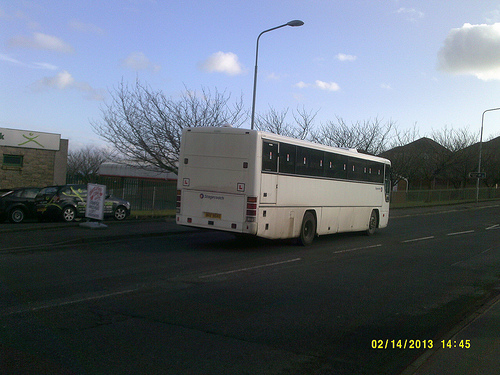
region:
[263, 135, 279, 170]
black window on bus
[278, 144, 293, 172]
black window on bus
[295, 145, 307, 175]
black window on bus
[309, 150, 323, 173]
black window on bus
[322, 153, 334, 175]
black window on bus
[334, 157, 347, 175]
black window on bus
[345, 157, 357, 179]
black window on bus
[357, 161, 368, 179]
black window on bus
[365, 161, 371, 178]
black window on bus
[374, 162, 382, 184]
black window on bus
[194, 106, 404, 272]
white bus on road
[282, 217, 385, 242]
black wheels on bus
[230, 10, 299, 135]
light pole behind bus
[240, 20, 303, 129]
light pole is grey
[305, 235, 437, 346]
road is dark grey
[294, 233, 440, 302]
white lines on road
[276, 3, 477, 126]
white and blue sky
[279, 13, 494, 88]
white clouds in sky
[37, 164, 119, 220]
green hybrid is parked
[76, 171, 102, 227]
white sign in front of hybrid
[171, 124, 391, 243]
white bus in street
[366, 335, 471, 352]
yellow time date stamp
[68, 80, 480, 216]
leafless brown trees in background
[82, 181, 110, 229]
large white sign on sidewalk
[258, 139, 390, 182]
bus has black tinted windows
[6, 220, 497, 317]
white lines painted in street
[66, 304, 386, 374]
large crack in street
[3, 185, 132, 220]
cars parked in parking lot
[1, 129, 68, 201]
brick building behind cars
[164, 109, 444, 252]
the bus is white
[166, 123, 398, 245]
the bus is white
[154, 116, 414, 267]
the bus is white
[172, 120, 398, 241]
the bus is white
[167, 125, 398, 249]
the bus is white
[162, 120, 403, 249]
the bus is white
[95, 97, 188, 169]
the tree is bare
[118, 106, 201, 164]
the tree is bare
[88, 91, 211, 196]
the tree is bare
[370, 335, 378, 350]
yellow print style number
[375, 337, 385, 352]
yellow print style number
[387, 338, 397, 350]
yellow print style number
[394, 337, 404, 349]
yellow print style number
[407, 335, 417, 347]
yellow print style number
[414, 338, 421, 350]
yellow print style number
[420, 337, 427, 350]
yellow print style number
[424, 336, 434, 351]
yellow print style number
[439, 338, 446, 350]
yellow print style number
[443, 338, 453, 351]
yellow print style number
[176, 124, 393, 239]
the bus is white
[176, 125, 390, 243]
the bus is dirty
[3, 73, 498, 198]
the trees are bare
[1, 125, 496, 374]
the bus on the road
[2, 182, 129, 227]
the cars are parked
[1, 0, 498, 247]
the blue sky above the bus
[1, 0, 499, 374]
the blue sky above the bus on the road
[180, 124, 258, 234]
back of a bus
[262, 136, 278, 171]
window of a bus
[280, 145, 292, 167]
window of a bus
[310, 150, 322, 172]
window of a bus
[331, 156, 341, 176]
window of a bus